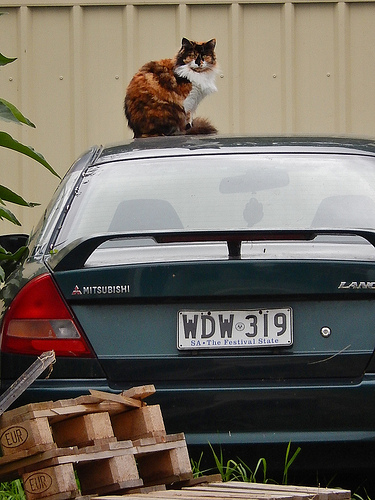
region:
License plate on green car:
[177, 307, 292, 349]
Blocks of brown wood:
[8, 410, 181, 496]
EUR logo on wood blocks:
[2, 426, 33, 450]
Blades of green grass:
[194, 454, 303, 478]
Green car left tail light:
[14, 278, 94, 371]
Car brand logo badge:
[69, 281, 134, 293]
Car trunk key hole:
[320, 323, 331, 336]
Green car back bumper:
[86, 354, 367, 450]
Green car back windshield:
[90, 164, 369, 225]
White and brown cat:
[126, 41, 226, 146]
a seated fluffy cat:
[122, 35, 220, 137]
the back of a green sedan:
[0, 135, 373, 485]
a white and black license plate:
[175, 305, 295, 347]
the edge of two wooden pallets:
[0, 383, 192, 497]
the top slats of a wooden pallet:
[72, 478, 348, 497]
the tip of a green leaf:
[0, 51, 19, 69]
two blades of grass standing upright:
[281, 440, 300, 484]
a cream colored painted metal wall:
[0, 0, 373, 235]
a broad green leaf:
[0, 129, 63, 179]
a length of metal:
[0, 349, 54, 415]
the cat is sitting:
[125, 37, 230, 134]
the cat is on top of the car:
[20, 136, 374, 484]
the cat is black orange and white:
[115, 36, 229, 134]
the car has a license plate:
[12, 135, 373, 463]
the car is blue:
[5, 134, 374, 499]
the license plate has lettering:
[170, 309, 299, 351]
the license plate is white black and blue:
[174, 310, 296, 348]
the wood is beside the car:
[4, 386, 348, 498]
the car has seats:
[3, 136, 374, 472]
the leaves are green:
[0, 97, 60, 266]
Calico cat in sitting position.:
[122, 38, 222, 137]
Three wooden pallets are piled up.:
[0, 380, 349, 496]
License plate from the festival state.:
[177, 306, 297, 346]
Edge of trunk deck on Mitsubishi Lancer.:
[50, 259, 374, 301]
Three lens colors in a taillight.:
[1, 273, 95, 356]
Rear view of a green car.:
[2, 132, 373, 468]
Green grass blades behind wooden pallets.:
[0, 438, 373, 498]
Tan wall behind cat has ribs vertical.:
[0, 0, 374, 236]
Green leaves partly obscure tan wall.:
[0, 45, 64, 293]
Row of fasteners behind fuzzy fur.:
[4, 73, 372, 82]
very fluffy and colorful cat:
[118, 36, 231, 139]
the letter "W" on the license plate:
[181, 311, 200, 342]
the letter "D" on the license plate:
[200, 311, 215, 340]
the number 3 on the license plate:
[241, 310, 259, 338]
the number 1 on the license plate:
[257, 309, 272, 339]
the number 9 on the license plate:
[271, 309, 289, 337]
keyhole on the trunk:
[316, 320, 335, 341]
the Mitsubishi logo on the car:
[68, 278, 133, 301]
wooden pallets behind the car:
[7, 379, 352, 498]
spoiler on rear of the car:
[40, 224, 374, 266]